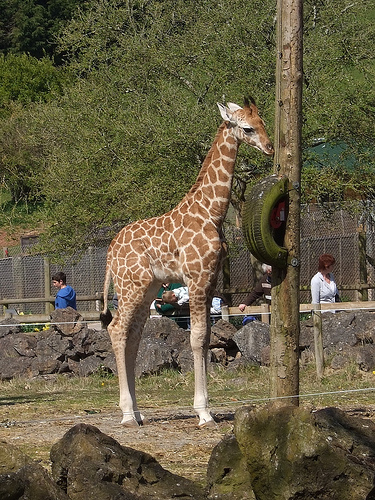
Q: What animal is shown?
A: Giraffe.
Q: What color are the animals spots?
A: Brown.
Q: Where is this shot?
A: Zoo.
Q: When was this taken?
A: Daytime.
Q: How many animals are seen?
A: 1.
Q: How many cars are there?
A: 0.